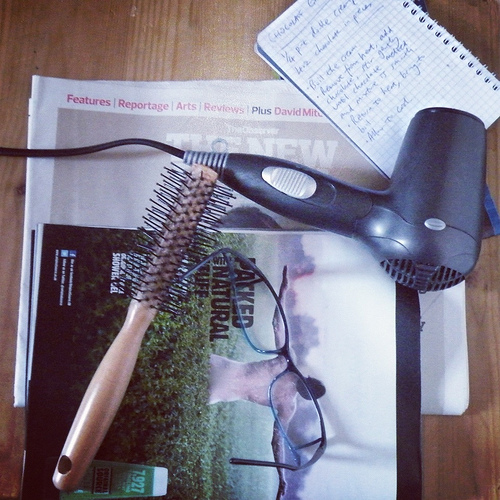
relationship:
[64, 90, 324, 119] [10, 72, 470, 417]
writings on magazine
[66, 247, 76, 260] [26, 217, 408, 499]
logo on magazines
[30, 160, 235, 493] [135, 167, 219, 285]
brown hairbrush with brissles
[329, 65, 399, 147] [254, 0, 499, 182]
written on notepad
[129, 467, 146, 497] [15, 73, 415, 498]
numbers on magazine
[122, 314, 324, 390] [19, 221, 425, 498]
person items are on newspaper and magazine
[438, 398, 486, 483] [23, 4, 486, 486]
woodgrain on desk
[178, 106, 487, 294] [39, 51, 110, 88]
blowdryer on table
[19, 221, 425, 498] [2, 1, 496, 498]
magazine on table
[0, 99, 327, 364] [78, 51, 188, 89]
notebook on table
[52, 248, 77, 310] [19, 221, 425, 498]
logo on magazine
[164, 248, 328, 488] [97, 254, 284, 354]
eyeglasses on top of magazine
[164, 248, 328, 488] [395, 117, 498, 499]
eyeglasses on table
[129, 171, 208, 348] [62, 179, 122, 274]
hair brush on table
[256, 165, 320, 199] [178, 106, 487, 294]
switch on blowdryer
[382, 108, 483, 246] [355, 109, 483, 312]
top belonging to hair dryer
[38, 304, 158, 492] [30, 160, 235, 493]
brush handle belonging to brown hairbrush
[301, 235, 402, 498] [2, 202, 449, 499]
part belonging to magazine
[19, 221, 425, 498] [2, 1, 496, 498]
magazine lying on top of table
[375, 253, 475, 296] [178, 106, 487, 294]
vent belonging to blowdryer